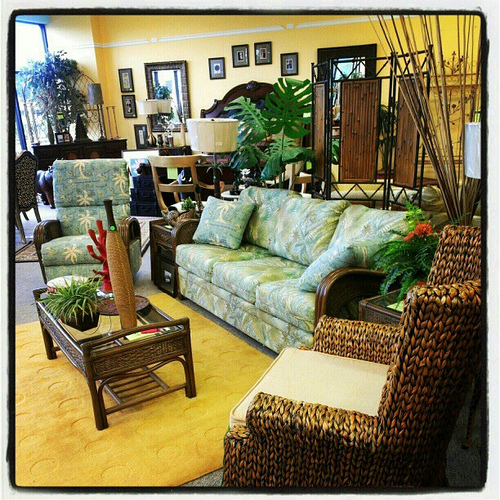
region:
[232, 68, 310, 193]
a tall fake plant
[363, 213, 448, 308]
fake flower on a table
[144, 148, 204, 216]
a wood chair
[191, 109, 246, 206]
a lamp with a white shade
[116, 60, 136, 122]
pictures hanging on the wall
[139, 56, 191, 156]
a mirror in a frame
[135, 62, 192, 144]
a mirror hanging on a wall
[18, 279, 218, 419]
a wood coffee table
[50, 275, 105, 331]
a green plant in a pot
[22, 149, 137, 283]
a chair with palm trees on it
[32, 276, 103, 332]
A green leaf plant in a dark brown planter.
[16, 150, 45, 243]
The back of a fancy dark brown table chair.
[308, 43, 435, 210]
A black metal and bamboo screen.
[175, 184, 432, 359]
A three seat palm tree couch.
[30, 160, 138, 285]
A palm tree patterned chair with brown arms.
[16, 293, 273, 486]
A thick yellow rug with circles on it.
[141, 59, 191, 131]
A large brown trim mirror on the wall.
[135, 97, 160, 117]
A white lamp shade in front of a large mirror.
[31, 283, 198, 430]
A brown wicker coffee table with decorations on top.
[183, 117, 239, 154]
A white round lampshade to the back left of a couch.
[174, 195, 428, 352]
a green palm tree patterned couch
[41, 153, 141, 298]
a green palm tree patterned chair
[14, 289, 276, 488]
a yellow rug in front of a couch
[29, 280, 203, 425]
a coffee table in front of a couch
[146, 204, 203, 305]
a side table next to a couch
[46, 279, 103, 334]
a potted plant on a coffee table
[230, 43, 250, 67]
a square picture above a bed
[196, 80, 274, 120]
a dark wood headboard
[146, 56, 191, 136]
rectangular mirror on a wall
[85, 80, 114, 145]
a lamp on a dresser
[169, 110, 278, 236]
beige table lamp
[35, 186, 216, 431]
woven brown table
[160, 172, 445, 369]
green tropical printed couch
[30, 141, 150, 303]
green printed tropical chair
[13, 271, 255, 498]
yellow rug under table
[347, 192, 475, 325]
pot plant on table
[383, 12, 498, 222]
long sticks in vase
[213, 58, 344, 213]
leafed plant in pot plant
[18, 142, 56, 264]
black dining room chair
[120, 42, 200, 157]
framed mirror on the wall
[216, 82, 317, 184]
a large potted palm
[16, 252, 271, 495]
bright yellow area rug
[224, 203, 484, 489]
woven wicker livingroom furniture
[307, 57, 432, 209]
Bamboo room divider in black frame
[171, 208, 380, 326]
rattan arms on sofa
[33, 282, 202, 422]
rattan and woven wicker coffee table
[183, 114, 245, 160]
white shallow drum lamp shade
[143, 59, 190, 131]
mirror framed in woven wicker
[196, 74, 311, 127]
a dark wood headboard against wall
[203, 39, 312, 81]
wall pictures hung in a curve